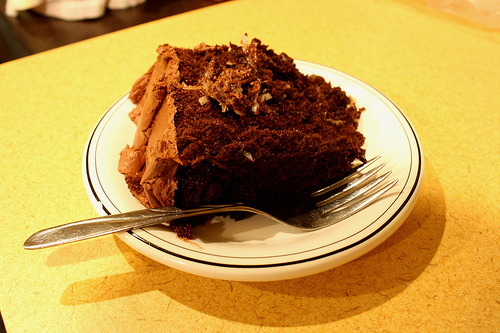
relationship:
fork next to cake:
[22, 155, 400, 251] [117, 32, 369, 240]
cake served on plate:
[117, 32, 369, 240] [81, 60, 425, 284]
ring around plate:
[85, 66, 422, 270] [81, 60, 425, 284]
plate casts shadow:
[81, 60, 425, 284] [114, 155, 447, 327]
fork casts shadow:
[22, 155, 400, 251] [45, 233, 160, 306]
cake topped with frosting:
[117, 32, 369, 240] [117, 43, 181, 210]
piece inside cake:
[198, 94, 211, 105] [117, 32, 369, 240]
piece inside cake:
[259, 91, 273, 103] [117, 32, 369, 240]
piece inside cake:
[240, 33, 249, 50] [117, 32, 369, 240]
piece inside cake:
[241, 149, 257, 165] [117, 32, 369, 240]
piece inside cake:
[219, 102, 228, 112] [117, 32, 369, 240]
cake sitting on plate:
[117, 32, 369, 240] [81, 60, 425, 284]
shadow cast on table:
[114, 155, 447, 327] [1, 1, 500, 332]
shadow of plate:
[114, 155, 447, 327] [81, 60, 425, 284]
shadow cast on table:
[45, 233, 160, 306] [1, 1, 500, 332]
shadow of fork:
[45, 233, 160, 306] [22, 155, 400, 251]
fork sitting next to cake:
[22, 155, 400, 251] [117, 32, 369, 240]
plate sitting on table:
[81, 60, 425, 284] [1, 1, 500, 332]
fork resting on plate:
[22, 155, 400, 251] [81, 60, 425, 284]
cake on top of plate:
[117, 32, 369, 240] [81, 60, 425, 284]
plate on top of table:
[81, 60, 425, 284] [1, 1, 500, 332]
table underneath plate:
[1, 1, 500, 332] [81, 60, 425, 284]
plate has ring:
[81, 60, 425, 284] [85, 66, 422, 270]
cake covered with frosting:
[117, 32, 369, 240] [117, 43, 181, 210]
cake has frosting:
[117, 32, 369, 240] [117, 43, 181, 210]